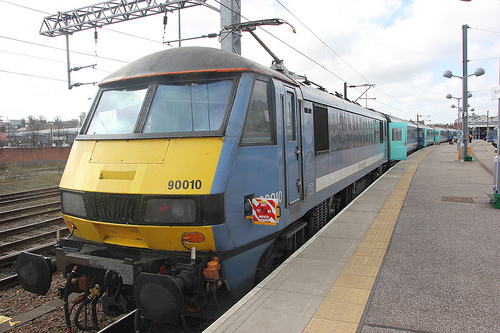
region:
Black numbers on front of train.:
[164, 173, 232, 208]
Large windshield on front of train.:
[97, 84, 230, 131]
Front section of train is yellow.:
[68, 141, 209, 198]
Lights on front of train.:
[49, 189, 193, 240]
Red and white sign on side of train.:
[243, 193, 296, 230]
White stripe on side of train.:
[323, 160, 380, 180]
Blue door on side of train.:
[268, 102, 308, 207]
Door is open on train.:
[382, 119, 411, 146]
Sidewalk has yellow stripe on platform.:
[350, 201, 372, 331]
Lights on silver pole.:
[443, 64, 498, 84]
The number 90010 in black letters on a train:
[166, 177, 202, 190]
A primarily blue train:
[17, 47, 498, 330]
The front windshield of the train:
[82, 75, 237, 137]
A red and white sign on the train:
[246, 196, 279, 226]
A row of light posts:
[442, 22, 485, 162]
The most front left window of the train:
[239, 77, 276, 144]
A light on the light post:
[442, 70, 464, 80]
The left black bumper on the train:
[134, 270, 186, 321]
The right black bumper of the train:
[12, 248, 55, 293]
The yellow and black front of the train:
[58, 140, 224, 249]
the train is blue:
[207, 79, 391, 215]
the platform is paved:
[412, 190, 475, 325]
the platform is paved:
[393, 159, 496, 315]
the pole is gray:
[449, 34, 482, 160]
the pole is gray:
[455, 26, 473, 191]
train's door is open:
[376, 100, 421, 175]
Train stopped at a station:
[14, 42, 491, 322]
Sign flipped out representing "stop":
[221, 183, 297, 239]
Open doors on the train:
[381, 115, 446, 167]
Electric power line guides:
[0, 5, 396, 106]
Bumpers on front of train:
[6, 236, 221, 331]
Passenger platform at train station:
[206, 132, 494, 329]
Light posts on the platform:
[432, 22, 493, 169]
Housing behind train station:
[0, 104, 90, 153]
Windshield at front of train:
[79, 80, 276, 142]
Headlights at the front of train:
[46, 180, 235, 232]